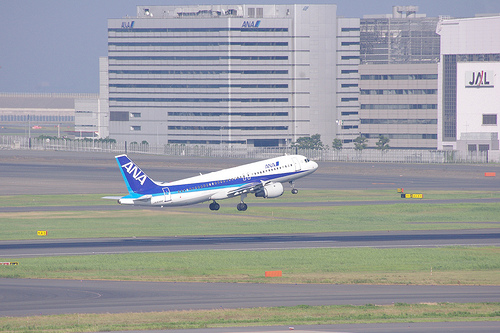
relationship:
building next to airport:
[102, 4, 343, 143] [6, 87, 101, 149]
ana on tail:
[121, 162, 147, 185] [116, 150, 158, 193]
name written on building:
[237, 18, 263, 31] [102, 4, 343, 143]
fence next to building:
[0, 131, 497, 167] [102, 4, 343, 143]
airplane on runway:
[103, 153, 319, 210] [4, 217, 499, 258]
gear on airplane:
[209, 203, 220, 210] [103, 153, 319, 210]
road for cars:
[1, 119, 74, 132] [27, 124, 45, 132]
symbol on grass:
[265, 268, 284, 278] [1, 240, 499, 282]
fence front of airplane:
[0, 131, 497, 167] [103, 153, 319, 210]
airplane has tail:
[103, 153, 319, 210] [116, 150, 158, 193]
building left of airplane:
[102, 4, 343, 143] [103, 153, 319, 210]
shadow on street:
[8, 162, 124, 174] [1, 162, 500, 189]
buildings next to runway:
[340, 9, 499, 149] [4, 217, 499, 258]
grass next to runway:
[1, 240, 499, 282] [4, 217, 499, 258]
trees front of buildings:
[268, 128, 395, 150] [340, 9, 499, 149]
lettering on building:
[469, 70, 489, 85] [431, 15, 499, 156]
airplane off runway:
[103, 153, 319, 210] [4, 217, 499, 258]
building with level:
[102, 4, 343, 143] [105, 30, 293, 40]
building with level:
[102, 4, 343, 143] [108, 69, 290, 81]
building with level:
[102, 4, 343, 143] [108, 53, 290, 64]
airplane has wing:
[103, 153, 319, 210] [99, 194, 122, 201]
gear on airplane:
[205, 202, 250, 214] [103, 153, 319, 210]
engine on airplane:
[253, 178, 288, 199] [103, 153, 319, 210]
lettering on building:
[462, 68, 491, 87] [431, 15, 499, 156]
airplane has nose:
[105, 143, 322, 213] [300, 157, 319, 175]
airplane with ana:
[105, 143, 322, 213] [121, 162, 147, 185]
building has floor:
[102, 4, 343, 143] [108, 98, 291, 108]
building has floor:
[102, 4, 343, 143] [113, 47, 291, 58]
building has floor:
[102, 4, 343, 143] [110, 88, 289, 98]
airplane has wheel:
[105, 143, 322, 213] [206, 199, 214, 210]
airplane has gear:
[105, 143, 322, 213] [209, 203, 220, 210]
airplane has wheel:
[105, 143, 322, 213] [237, 203, 242, 210]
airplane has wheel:
[105, 143, 322, 213] [242, 202, 248, 210]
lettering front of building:
[469, 70, 489, 85] [431, 15, 499, 156]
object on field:
[401, 191, 428, 199] [5, 183, 496, 329]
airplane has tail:
[105, 143, 322, 213] [116, 150, 158, 193]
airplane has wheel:
[105, 143, 322, 213] [291, 188, 301, 194]